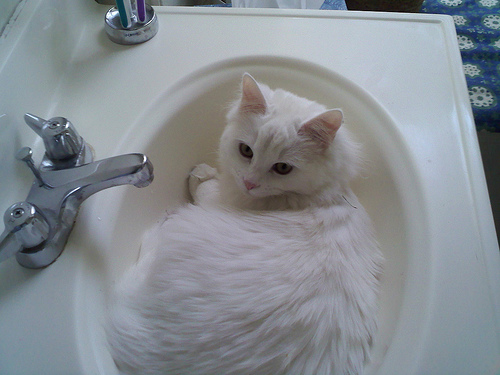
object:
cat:
[106, 66, 379, 375]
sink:
[0, 6, 498, 375]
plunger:
[13, 146, 53, 189]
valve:
[22, 109, 81, 159]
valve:
[0, 199, 48, 263]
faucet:
[54, 148, 155, 201]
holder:
[96, 4, 162, 46]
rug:
[423, 0, 500, 119]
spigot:
[120, 151, 155, 188]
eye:
[273, 160, 296, 176]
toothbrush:
[131, 0, 152, 29]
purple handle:
[135, 2, 148, 27]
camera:
[149, 349, 323, 364]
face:
[216, 106, 325, 200]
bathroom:
[2, 3, 500, 373]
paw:
[188, 163, 223, 196]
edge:
[436, 12, 500, 240]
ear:
[296, 109, 342, 153]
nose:
[243, 175, 261, 194]